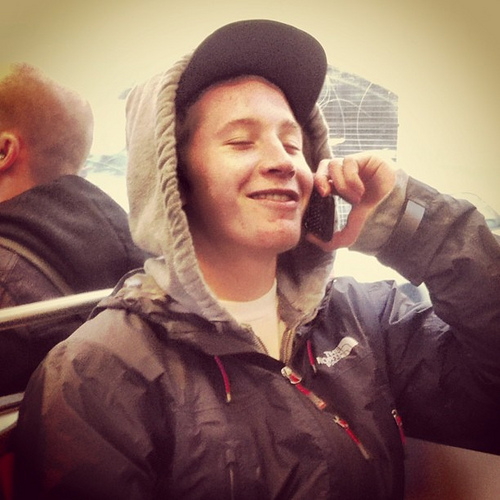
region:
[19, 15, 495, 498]
guy in a hooded jacket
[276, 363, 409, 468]
jacket has numerous zippers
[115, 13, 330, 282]
baseball cap under a hood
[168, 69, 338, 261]
guy is holding a cellphone to his ear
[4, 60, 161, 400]
a man sits with his back to the main character in the picture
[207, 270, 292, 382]
white shirt under a hoodie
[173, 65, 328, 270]
guy is smiling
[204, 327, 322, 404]
hood ties are red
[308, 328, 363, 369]
manufacturers logo on jacket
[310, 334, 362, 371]
jacket was made by The North Face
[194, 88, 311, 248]
The face of a smiling man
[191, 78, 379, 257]
A man talking on a cell phone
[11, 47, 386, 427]
Two people sitting back to back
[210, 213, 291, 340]
A person wearing a white t-shirt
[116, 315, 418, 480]
A black wind breaker with logo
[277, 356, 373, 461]
Red zippers on a wind breaker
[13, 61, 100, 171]
The back of a person's head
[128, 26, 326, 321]
A man wearing a grey hoodie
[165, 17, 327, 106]
The front of a black baseball cap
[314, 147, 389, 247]
A hand holding a cell phone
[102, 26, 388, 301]
the man is holding the phone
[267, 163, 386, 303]
the phone is black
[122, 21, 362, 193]
the cap is black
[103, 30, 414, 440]
the hood is gray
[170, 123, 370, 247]
man's eyes are closed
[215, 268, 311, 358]
the shirt is white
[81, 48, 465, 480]
man is wearing a jacket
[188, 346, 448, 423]
the strings are red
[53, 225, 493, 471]
the jacket is black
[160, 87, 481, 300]
the man is smiling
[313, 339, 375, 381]
Northface jacket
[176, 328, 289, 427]
Red pull string for jacket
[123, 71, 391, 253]
young boy on his phone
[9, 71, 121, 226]
Man in the background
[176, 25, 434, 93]
Hat worn by the young man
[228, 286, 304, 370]
White shirt underneath the jacket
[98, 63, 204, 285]
Young boy wearing hood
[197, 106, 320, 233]
Young guy smiling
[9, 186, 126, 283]
Hood for guy in the back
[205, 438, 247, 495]
Zipper in front of Jacket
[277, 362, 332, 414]
red zipper on boy's coat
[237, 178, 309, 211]
goofy grin on boy's face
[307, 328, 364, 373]
brand name logo on jacket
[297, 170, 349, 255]
cell phone in boy's hand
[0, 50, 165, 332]
man sitting behind boy talking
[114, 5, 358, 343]
grey hoodie on boy's head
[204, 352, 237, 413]
red tie pull on boy's jacket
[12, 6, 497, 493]
boy talking on cell phone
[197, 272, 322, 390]
white t-shirt under boy's jacket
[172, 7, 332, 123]
blue hat under grey hoodie